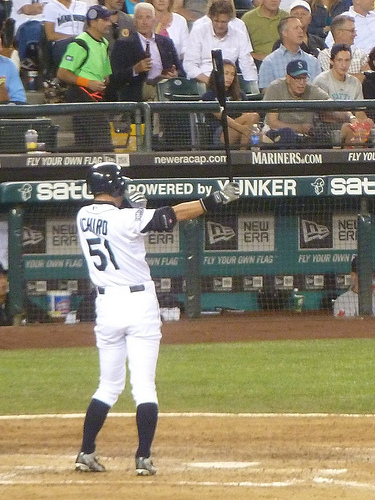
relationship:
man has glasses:
[262, 61, 358, 151] [287, 72, 309, 83]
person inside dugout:
[335, 257, 374, 322] [0, 173, 374, 322]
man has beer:
[111, 2, 188, 149] [143, 41, 152, 71]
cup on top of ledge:
[330, 130, 343, 149] [2, 147, 374, 171]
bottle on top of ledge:
[250, 123, 262, 151] [2, 147, 374, 171]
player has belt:
[75, 162, 240, 475] [96, 281, 155, 293]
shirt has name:
[75, 202, 155, 286] [78, 215, 108, 236]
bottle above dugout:
[250, 123, 262, 151] [0, 173, 374, 322]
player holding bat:
[75, 162, 240, 475] [210, 49, 238, 201]